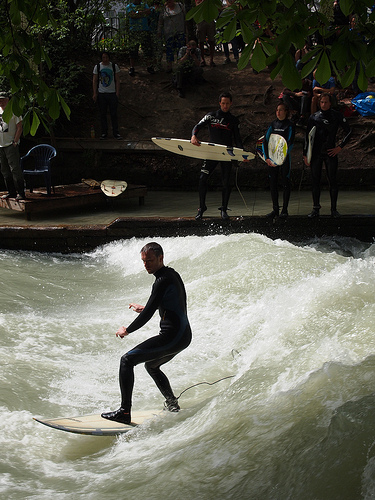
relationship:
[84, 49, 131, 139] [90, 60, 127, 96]
man wears shirt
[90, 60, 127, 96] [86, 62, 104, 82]
shirt has sleeve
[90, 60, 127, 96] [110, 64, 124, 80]
shirt has sleeve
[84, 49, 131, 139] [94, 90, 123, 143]
man wears pants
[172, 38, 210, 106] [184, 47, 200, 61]
man has camera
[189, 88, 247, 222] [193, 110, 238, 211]
man wears wetsuit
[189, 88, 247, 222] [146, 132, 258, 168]
man has surfboard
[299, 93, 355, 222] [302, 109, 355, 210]
man wears wetsuit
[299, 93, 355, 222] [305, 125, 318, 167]
man has surfboard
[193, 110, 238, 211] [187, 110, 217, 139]
wetsuit has sleeve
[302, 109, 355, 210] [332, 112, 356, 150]
wetsuit has sleeve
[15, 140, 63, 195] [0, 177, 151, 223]
chair on platform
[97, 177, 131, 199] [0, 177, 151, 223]
surfboard on platform